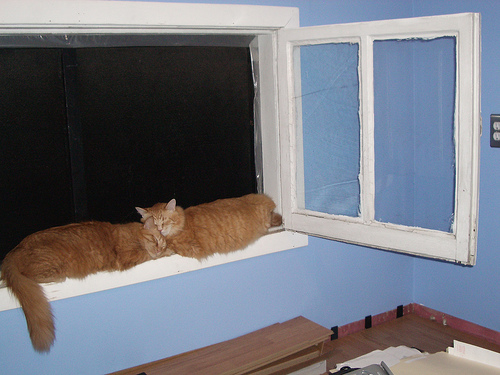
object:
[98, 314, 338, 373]
flooring panels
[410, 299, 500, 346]
red strip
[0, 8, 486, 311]
frame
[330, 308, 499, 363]
wood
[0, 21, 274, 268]
window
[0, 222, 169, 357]
cat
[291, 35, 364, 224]
window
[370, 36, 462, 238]
glass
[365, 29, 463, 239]
pane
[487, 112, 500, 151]
outlet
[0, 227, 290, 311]
window sill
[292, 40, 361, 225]
pane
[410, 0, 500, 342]
wall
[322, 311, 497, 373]
floor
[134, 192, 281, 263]
cat